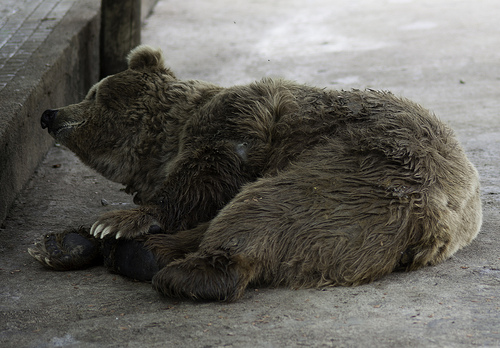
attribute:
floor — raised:
[3, 1, 124, 238]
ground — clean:
[159, 4, 498, 77]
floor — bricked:
[10, 10, 75, 71]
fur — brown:
[277, 152, 423, 227]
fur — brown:
[42, 42, 486, 321]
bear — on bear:
[33, 52, 483, 322]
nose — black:
[35, 102, 65, 135]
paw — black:
[44, 226, 98, 261]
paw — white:
[87, 210, 148, 240]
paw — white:
[26, 220, 99, 269]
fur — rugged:
[292, 193, 362, 242]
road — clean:
[0, 0, 499, 346]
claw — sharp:
[115, 232, 122, 239]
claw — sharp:
[100, 226, 112, 237]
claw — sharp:
[93, 220, 108, 237]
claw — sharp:
[90, 220, 99, 234]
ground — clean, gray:
[0, 0, 498, 346]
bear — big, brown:
[28, 44, 486, 305]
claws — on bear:
[86, 217, 124, 241]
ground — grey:
[347, 283, 448, 343]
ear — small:
[131, 46, 165, 76]